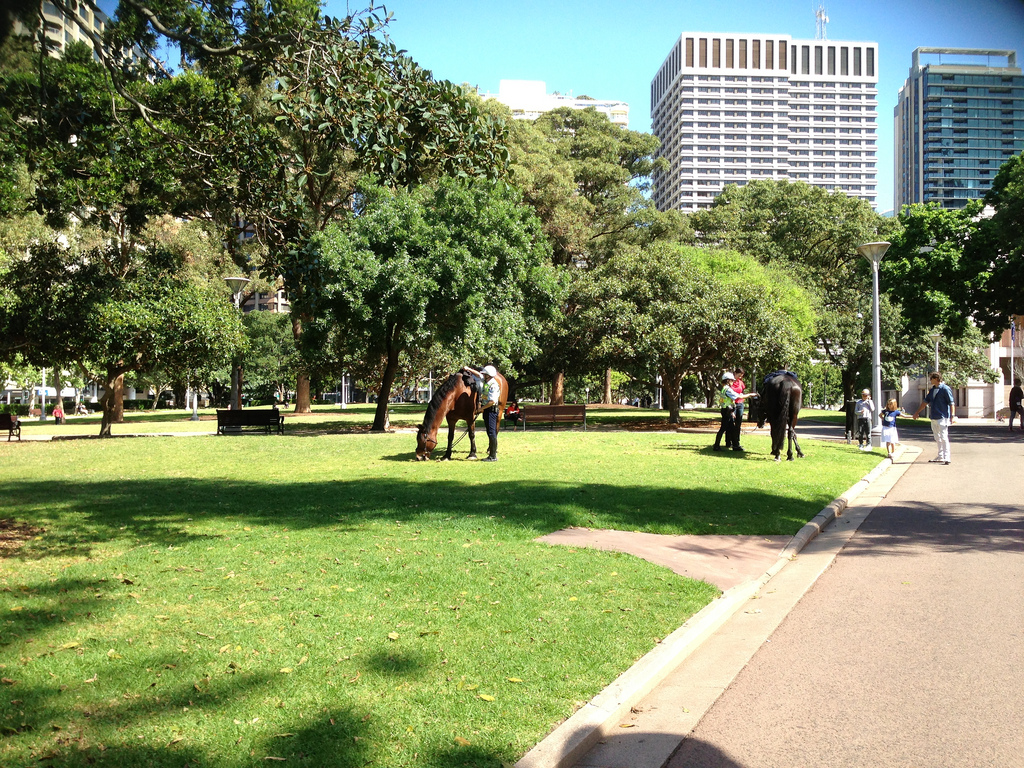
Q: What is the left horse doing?
A: Grazing grass.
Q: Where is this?
A: Park.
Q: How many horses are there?
A: Two.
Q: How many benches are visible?
A: 2.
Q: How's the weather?
A: Sunny.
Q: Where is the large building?
A: Behind the trees.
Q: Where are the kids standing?
A: Under the light post.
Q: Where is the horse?
A: In the park.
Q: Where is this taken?
A: A city park.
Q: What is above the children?
A: A tall lamp post.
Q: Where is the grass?
A: In the park.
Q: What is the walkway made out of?
A: Asphalt.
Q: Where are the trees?
A: In the city park.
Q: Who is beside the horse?
A: The rider.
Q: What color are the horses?
A: Brown.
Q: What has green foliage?
A: Trees.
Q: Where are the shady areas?
A: Lawn.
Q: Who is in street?
A: Adult with child.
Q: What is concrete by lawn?
A: Separates lawn and road.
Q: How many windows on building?
A: Many windows.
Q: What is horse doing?
A: Eating grass.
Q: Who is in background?
A: The people.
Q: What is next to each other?
A: 2 buildings.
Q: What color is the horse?
A: Brown.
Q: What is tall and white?
A: A building.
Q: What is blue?
A: Sky.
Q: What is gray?
A: Pavement.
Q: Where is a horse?
A: On the grass.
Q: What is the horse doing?
A: Eating grass.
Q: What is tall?
A: Buildings.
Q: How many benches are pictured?
A: Two.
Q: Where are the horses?
A: On the grass.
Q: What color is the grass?
A: Green.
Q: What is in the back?
A: Tall buildings.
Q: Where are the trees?
A: Behind the horses.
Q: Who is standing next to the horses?
A: A man.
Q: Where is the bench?
A: Under the trees.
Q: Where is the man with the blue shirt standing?
A: On the sidewalk.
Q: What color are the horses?
A: Brown.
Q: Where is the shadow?
A: On the grass.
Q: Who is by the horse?
A: A woman.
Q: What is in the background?
A: Buildings.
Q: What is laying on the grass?
A: Leaves.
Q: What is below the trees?
A: A park bench.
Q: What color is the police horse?
A: Brown.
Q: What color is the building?
A: White.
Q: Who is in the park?
A: People and horses.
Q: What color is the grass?
A: Green.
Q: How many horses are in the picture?
A: 1.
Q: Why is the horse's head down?
A: Grazing.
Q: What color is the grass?
A: Green.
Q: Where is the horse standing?
A: Grass.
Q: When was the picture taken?
A: During the day.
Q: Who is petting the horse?
A: A man.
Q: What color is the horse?
A: Brown.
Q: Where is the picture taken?
A: City park.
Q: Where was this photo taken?
A: The park.